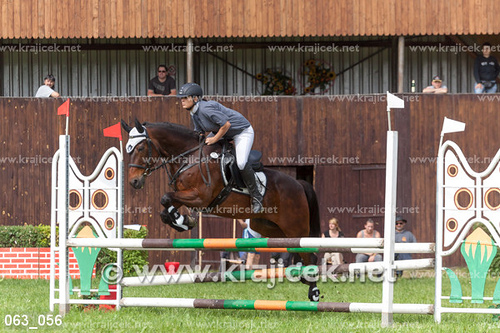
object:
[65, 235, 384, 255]
hurdle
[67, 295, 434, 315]
hurdle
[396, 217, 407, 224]
hat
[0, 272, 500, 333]
grass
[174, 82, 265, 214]
woman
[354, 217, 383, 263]
man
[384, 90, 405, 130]
white flag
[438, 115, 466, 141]
white flag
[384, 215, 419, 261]
man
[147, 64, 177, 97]
man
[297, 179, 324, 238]
tail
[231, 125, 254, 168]
pants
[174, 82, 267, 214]
jockey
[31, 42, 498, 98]
spectators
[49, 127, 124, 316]
pole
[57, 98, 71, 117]
flag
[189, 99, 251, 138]
shirt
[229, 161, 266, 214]
boots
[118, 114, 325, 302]
horse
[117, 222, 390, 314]
rail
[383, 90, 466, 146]
flags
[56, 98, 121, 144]
flag markers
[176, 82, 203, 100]
hat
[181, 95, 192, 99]
sunglasses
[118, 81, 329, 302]
competition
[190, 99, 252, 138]
vest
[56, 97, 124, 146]
markers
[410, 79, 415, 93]
beer